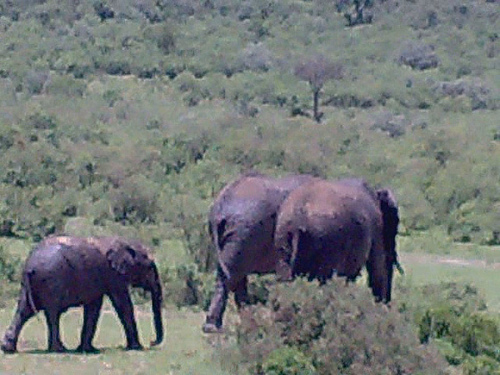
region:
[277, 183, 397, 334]
A large elephant walking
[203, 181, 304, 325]
A large elephant walking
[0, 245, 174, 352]
A baby elephant walking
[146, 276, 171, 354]
The baby elephants trunk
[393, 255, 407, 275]
The tusk of the larger elephant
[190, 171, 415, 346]
Two elephants walking side by side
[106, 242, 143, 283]
The ear of the baby elephant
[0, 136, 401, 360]
Three elephants walking togehter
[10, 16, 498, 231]
The trees behind the elephants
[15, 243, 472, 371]
The feild the elephants are walking in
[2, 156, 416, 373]
elephants on a field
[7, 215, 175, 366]
a baby elephant on a field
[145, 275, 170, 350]
long trunk of elephant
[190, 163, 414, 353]
two elephants walking together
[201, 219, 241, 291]
long tail of elephant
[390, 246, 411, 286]
tusk of an elephant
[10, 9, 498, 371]
field is covered with bushes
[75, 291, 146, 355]
front legs of elephant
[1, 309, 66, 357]
back legs of elephant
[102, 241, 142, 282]
right ear of elephant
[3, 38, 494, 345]
picture out of focus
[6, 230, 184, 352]
smaller elephant following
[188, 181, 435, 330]
two larger elephants walking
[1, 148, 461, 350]
three elephants walking in the grass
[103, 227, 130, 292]
ear is large and gray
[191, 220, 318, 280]
tails are long on animals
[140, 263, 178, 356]
baby elephant's trunk on the ground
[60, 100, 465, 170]
trees in the distnace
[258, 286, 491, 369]
bushes in back of animals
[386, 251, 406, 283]
tusk on the elephant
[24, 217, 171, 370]
small brown elephant walking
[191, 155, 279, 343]
large brown elephant walking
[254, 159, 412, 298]
large brown elephant walking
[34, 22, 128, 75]
tall green bushes on ground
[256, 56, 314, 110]
tall green bushes on ground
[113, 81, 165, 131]
tall green bushes on ground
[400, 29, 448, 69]
tall green bushes on ground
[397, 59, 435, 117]
tall green bushes on ground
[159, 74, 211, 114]
tall green bushes on ground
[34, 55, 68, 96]
tall green bushes on ground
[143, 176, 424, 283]
two large elepants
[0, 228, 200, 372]
baby elephant following big elephants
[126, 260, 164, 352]
trunk is long on baby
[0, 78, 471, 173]
bushes in the distance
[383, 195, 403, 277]
large ears on animal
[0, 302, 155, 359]
four legs on baby elephant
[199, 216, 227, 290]
tail is long on elephant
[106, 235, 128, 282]
ears are gray on baby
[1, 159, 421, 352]
three elephants walking thru the grass